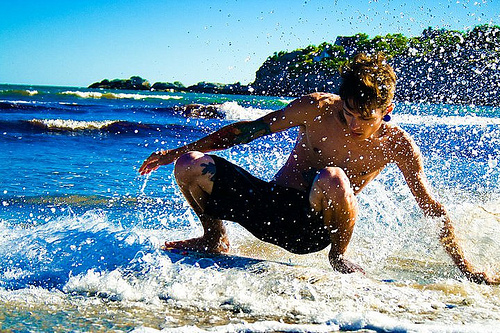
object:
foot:
[328, 248, 365, 288]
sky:
[122, 20, 217, 75]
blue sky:
[0, 0, 497, 84]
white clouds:
[166, 57, 255, 80]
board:
[135, 235, 498, 304]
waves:
[137, 90, 499, 198]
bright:
[83, 127, 98, 149]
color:
[53, 131, 81, 148]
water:
[41, 124, 113, 166]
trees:
[412, 33, 472, 109]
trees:
[257, 45, 443, 96]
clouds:
[109, 27, 249, 82]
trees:
[251, 22, 498, 102]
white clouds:
[204, 28, 261, 70]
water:
[7, 129, 137, 194]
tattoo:
[195, 112, 287, 147]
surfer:
[135, 48, 498, 289]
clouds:
[164, 31, 211, 63]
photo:
[28, 26, 442, 284]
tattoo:
[197, 157, 223, 186]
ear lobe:
[384, 112, 391, 122]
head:
[331, 52, 396, 138]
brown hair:
[336, 48, 403, 110]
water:
[2, 99, 488, 324]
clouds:
[225, 52, 255, 79]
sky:
[20, 20, 124, 57]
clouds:
[39, 25, 260, 85]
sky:
[2, 2, 496, 84]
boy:
[132, 56, 498, 291]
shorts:
[203, 147, 335, 262]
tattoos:
[162, 113, 272, 153]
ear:
[381, 105, 395, 122]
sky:
[17, 3, 495, 110]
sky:
[79, 30, 107, 48]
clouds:
[72, 0, 256, 55]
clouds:
[233, 59, 264, 69]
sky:
[74, 21, 246, 65]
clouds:
[203, 39, 249, 52]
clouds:
[160, 12, 260, 72]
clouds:
[37, 32, 77, 58]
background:
[11, 16, 484, 96]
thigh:
[184, 149, 267, 201]